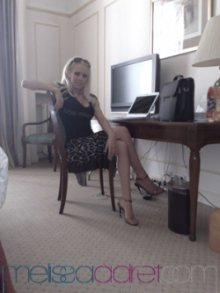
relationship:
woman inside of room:
[22, 56, 165, 226] [0, 1, 219, 293]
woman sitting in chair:
[22, 56, 165, 226] [46, 91, 116, 215]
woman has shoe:
[22, 56, 165, 226] [118, 198, 139, 227]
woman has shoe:
[22, 56, 165, 226] [136, 178, 164, 200]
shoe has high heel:
[118, 198, 139, 227] [118, 204, 121, 219]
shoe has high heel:
[136, 178, 164, 200] [134, 182, 142, 195]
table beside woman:
[109, 114, 219, 241] [22, 56, 165, 226]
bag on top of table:
[159, 75, 194, 123] [109, 114, 219, 241]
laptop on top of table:
[115, 93, 159, 120] [109, 114, 219, 241]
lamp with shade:
[191, 16, 219, 120] [192, 14, 219, 68]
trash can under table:
[167, 177, 191, 235] [109, 114, 219, 241]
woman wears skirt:
[22, 56, 165, 226] [64, 131, 103, 166]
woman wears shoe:
[22, 56, 165, 226] [118, 198, 139, 227]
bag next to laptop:
[159, 75, 194, 123] [115, 93, 159, 120]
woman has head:
[22, 56, 165, 226] [63, 57, 91, 91]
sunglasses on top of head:
[69, 57, 91, 67] [63, 57, 91, 91]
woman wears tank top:
[22, 56, 165, 226] [53, 83, 95, 139]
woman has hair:
[22, 56, 165, 226] [61, 58, 94, 105]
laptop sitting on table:
[115, 93, 159, 120] [109, 114, 219, 241]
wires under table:
[134, 137, 218, 209] [109, 114, 219, 241]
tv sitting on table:
[110, 54, 160, 112] [109, 114, 219, 241]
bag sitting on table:
[159, 75, 194, 123] [109, 114, 219, 241]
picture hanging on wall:
[150, 0, 214, 60] [69, 1, 219, 207]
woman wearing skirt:
[22, 56, 165, 226] [64, 131, 103, 166]